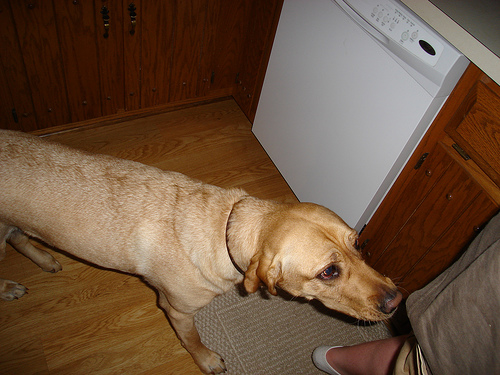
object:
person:
[311, 182, 499, 375]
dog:
[0, 129, 403, 373]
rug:
[183, 284, 399, 374]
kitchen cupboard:
[355, 74, 497, 300]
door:
[0, 2, 259, 135]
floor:
[0, 96, 297, 373]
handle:
[100, 5, 110, 37]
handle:
[126, 2, 138, 35]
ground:
[167, 99, 247, 130]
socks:
[403, 343, 429, 375]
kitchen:
[0, 0, 499, 375]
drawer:
[438, 75, 499, 189]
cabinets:
[0, 0, 277, 133]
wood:
[216, 17, 254, 90]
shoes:
[311, 336, 400, 373]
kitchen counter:
[394, 0, 498, 82]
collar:
[224, 192, 248, 276]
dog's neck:
[229, 186, 272, 290]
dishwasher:
[247, 0, 499, 299]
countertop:
[399, 0, 499, 90]